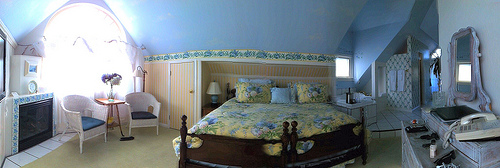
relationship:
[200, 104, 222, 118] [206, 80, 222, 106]
end table under a lamp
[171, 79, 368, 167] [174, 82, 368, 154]
bed has flowers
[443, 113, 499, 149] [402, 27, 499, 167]
phone on dresser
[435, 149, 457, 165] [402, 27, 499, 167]
sunglasses on dresser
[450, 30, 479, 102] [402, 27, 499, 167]
mirror on dresser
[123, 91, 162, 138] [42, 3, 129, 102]
chair near window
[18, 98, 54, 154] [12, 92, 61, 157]
fireplace has white trim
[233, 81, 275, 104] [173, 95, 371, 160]
pillow matches bedspread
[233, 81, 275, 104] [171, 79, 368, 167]
pillow on bed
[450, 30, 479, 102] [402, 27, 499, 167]
mirror on top of dresser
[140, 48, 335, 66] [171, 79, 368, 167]
wallpaper above bed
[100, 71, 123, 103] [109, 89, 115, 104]
flowers in vase